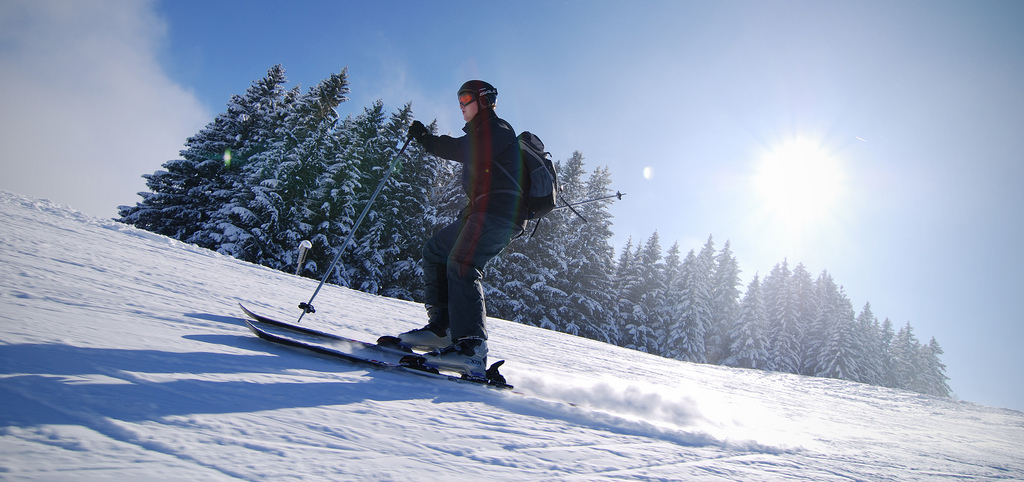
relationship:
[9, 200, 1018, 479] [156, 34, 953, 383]
snow near trees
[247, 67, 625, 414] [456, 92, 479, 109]
man wears goggles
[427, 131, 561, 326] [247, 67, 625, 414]
gear near man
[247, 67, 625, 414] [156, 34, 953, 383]
man near trees